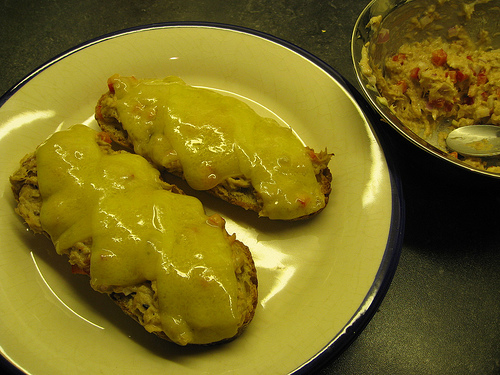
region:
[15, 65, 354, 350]
two sandwiches covered in melted cheese on a white plate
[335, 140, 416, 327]
the edge of a white plate with a blue ridge around the edge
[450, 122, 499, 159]
the end of a spoon in a bowl of sandwich filling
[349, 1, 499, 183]
a bowl containing sandwich filling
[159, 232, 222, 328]
shiny melted white cheese on top of the sandwich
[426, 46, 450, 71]
a piece of red tomato in the food in the bowl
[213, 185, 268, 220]
a part of the side of a crusty piece of bread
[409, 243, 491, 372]
a dark colored surface the dishes are sitting on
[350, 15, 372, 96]
the edge of the metal bowl containing the sandwich filling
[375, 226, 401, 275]
the dark blue edge of the plate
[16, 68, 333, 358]
Food on a plate.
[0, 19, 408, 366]
The plate is white.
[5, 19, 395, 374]
The plate is round.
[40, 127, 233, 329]
The cheese is white.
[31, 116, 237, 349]
The cheese is melted.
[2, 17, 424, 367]
Plate on a table.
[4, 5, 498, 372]
The plate is black.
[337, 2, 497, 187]
the bowl is silver.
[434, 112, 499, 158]
Spoon in a bowl.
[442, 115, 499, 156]
The spoon is silver.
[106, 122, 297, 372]
the plate is white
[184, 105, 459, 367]
the plate is white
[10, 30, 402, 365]
food smothered in creamy sauce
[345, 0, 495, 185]
pot with remaining cooked food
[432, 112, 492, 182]
used spoon inside of pot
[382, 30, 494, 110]
diced red ingredient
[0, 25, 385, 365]
yellow plate with black rim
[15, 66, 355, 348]
open-faced sandwiches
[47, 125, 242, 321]
light shining along sauce surface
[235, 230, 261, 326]
exposed brown crust of bread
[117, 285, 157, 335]
exposed sandwich filling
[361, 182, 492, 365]
black matte surface of table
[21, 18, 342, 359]
two chickens on a plate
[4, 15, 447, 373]
two cooked chickens on a plate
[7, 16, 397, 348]
two chickens with suace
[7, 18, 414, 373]
two chicks with sauce on top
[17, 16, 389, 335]
two baked chickens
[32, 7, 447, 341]
two baked chickens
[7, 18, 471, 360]
two cooked chickens on a white plate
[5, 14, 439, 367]
sauce on top of chicken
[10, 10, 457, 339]
white plate with chicken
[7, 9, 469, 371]
plate with cooked chicken